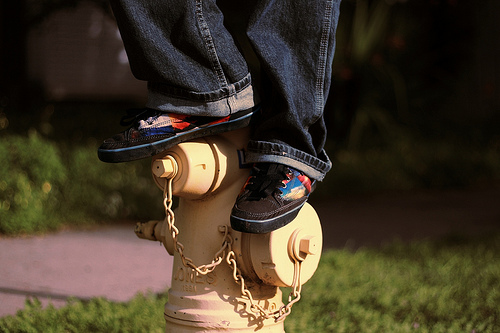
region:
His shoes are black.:
[103, 92, 329, 227]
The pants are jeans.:
[94, 2, 343, 192]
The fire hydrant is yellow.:
[125, 128, 324, 332]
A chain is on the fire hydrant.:
[153, 178, 308, 316]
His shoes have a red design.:
[133, 98, 200, 136]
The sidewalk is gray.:
[18, 183, 495, 278]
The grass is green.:
[4, 235, 496, 327]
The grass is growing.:
[10, 237, 497, 328]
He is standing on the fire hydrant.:
[98, 6, 346, 330]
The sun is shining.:
[3, 3, 499, 326]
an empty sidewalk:
[3, 184, 498, 312]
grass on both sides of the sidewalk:
[8, 127, 489, 332]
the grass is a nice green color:
[1, 108, 479, 329]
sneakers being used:
[90, 101, 322, 230]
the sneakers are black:
[99, 102, 322, 232]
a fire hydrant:
[131, 103, 338, 324]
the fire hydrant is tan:
[128, 70, 329, 328]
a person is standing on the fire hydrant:
[100, 14, 347, 329]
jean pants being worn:
[119, 17, 353, 162]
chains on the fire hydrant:
[157, 184, 306, 319]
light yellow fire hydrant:
[107, 114, 360, 331]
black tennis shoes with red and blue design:
[91, 100, 315, 240]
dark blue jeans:
[109, 1, 352, 178]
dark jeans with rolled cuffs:
[119, 20, 336, 177]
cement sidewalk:
[0, 167, 481, 317]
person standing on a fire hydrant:
[96, 21, 373, 330]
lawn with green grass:
[21, 223, 498, 331]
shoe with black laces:
[224, 162, 316, 238]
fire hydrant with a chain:
[124, 129, 362, 331]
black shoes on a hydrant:
[86, 10, 374, 331]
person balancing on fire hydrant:
[100, 0, 336, 232]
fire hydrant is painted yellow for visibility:
[132, 122, 317, 328]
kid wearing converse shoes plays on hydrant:
[95, 106, 316, 231]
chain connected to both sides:
[155, 150, 315, 318]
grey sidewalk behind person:
[2, 220, 170, 315]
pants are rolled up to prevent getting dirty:
[145, 70, 331, 181]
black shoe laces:
[127, 102, 287, 197]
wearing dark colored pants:
[125, 40, 330, 182]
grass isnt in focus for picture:
[0, 127, 491, 329]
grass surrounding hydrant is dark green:
[1, 241, 498, 331]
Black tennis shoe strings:
[222, 154, 332, 239]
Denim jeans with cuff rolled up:
[117, 11, 314, 188]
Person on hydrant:
[109, 67, 358, 283]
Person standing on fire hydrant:
[106, 12, 339, 293]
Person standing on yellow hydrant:
[123, 6, 343, 276]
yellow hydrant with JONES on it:
[145, 255, 240, 310]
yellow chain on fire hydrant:
[150, 155, 297, 326]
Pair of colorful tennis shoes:
[105, 83, 336, 228]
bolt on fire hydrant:
[277, 227, 337, 268]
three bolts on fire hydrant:
[102, 155, 326, 270]